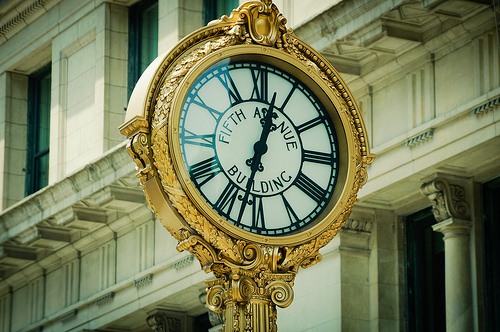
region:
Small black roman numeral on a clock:
[240, 58, 270, 101]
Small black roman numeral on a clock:
[211, 62, 245, 108]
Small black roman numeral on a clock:
[188, 93, 222, 123]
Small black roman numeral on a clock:
[180, 120, 218, 150]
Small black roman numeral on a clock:
[183, 157, 214, 183]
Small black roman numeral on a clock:
[210, 176, 234, 223]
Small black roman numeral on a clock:
[243, 182, 268, 233]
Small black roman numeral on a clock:
[270, 189, 299, 234]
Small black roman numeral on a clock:
[294, 166, 324, 213]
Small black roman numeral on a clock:
[297, 143, 338, 170]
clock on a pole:
[140, 15, 371, 256]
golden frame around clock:
[183, 10, 284, 60]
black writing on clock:
[228, 163, 298, 188]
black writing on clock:
[220, 101, 254, 141]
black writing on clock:
[257, 108, 304, 149]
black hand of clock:
[248, 98, 283, 152]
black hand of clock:
[220, 158, 267, 235]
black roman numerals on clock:
[261, 176, 329, 230]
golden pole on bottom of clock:
[205, 266, 287, 330]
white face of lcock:
[230, 113, 294, 168]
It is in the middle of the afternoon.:
[172, 60, 357, 238]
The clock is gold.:
[117, 10, 380, 328]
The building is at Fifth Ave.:
[211, 98, 306, 191]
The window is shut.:
[13, 66, 56, 192]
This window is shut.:
[398, 213, 439, 324]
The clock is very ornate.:
[116, 0, 376, 326]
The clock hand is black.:
[235, 86, 285, 221]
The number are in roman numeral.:
[165, 52, 351, 238]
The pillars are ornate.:
[421, 173, 481, 328]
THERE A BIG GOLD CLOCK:
[115, 0, 372, 328]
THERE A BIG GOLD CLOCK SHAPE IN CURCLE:
[137, 1, 369, 325]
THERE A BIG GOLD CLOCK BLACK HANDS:
[225, 82, 286, 232]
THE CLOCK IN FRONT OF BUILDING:
[0, 0, 497, 327]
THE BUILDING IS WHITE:
[0, 0, 498, 330]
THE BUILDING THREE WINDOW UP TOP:
[17, 0, 247, 198]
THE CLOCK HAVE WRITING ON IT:
[212, 99, 308, 191]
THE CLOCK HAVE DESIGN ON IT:
[115, 0, 373, 327]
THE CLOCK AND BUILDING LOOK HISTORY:
[0, 0, 495, 330]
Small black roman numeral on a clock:
[280, 76, 300, 118]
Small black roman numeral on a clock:
[295, 148, 342, 168]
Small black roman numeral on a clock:
[290, 171, 331, 203]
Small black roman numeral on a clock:
[273, 186, 307, 233]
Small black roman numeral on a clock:
[249, 189, 281, 264]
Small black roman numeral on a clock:
[210, 182, 255, 222]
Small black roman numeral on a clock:
[185, 156, 226, 191]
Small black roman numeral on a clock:
[176, 121, 240, 163]